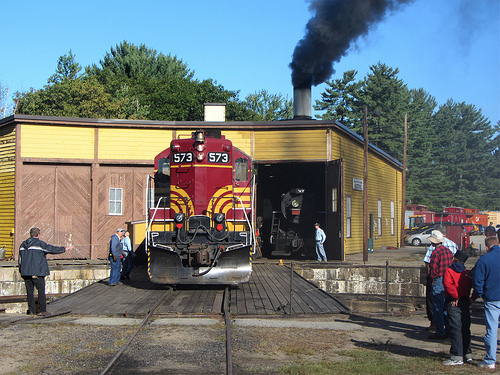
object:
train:
[145, 128, 259, 291]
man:
[470, 235, 500, 369]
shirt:
[429, 245, 453, 280]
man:
[426, 229, 455, 340]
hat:
[425, 230, 446, 244]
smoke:
[286, 1, 394, 90]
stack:
[292, 86, 312, 119]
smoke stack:
[292, 87, 312, 119]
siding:
[343, 133, 405, 254]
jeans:
[481, 300, 499, 365]